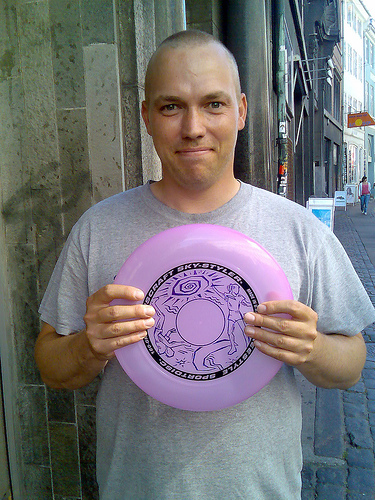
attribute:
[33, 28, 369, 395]
man — smiling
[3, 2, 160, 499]
wall — to left of man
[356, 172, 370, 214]
woman — walking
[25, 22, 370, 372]
man — nearly bald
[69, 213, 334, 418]
frisbee — pink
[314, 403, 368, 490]
fridge — brick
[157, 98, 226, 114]
eyes — green-brown, sparkly, happy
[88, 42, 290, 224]
face — happy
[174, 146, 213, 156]
lips — pressed, smiley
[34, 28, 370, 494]
man — happy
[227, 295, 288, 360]
nails — for fingers, manicured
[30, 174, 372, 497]
shirt — a tee, grey, pink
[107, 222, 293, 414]
frisbee — purple, pink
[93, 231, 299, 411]
frisbee — purple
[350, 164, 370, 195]
woman — dark haired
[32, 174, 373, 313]
gray shirt — a tee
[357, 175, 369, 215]
person — walking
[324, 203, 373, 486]
sidewalk — brick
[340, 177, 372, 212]
jacket — white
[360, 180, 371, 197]
shirt — pink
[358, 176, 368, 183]
hair — dark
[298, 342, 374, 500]
sidewalk — black